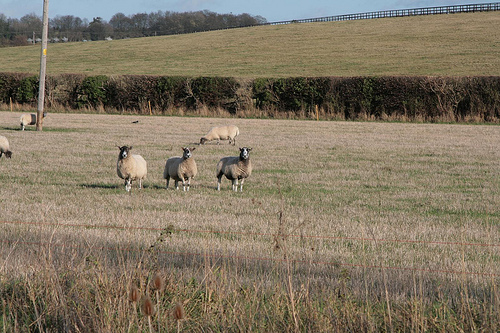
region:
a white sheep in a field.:
[110, 136, 150, 198]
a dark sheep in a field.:
[162, 138, 211, 200]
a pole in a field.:
[32, 0, 52, 136]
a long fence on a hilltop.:
[245, 0, 496, 28]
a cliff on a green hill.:
[0, 67, 494, 124]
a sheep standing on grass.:
[196, 140, 259, 201]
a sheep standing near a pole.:
[15, 101, 55, 136]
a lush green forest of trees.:
[0, 0, 265, 44]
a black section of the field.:
[132, 115, 157, 128]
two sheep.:
[0, 97, 61, 172]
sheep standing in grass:
[102, 138, 142, 203]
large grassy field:
[153, 34, 438, 71]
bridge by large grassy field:
[307, 2, 467, 21]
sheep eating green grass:
[197, 119, 244, 148]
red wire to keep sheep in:
[118, 216, 436, 300]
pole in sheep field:
[35, 12, 51, 134]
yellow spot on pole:
[41, 45, 49, 55]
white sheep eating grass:
[200, 112, 245, 144]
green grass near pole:
[45, 124, 90, 137]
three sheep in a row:
[110, 139, 261, 196]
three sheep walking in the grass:
[107, 141, 260, 193]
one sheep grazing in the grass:
[188, 120, 246, 147]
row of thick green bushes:
[0, 71, 497, 123]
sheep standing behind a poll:
[15, 105, 53, 128]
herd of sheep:
[0, 102, 279, 212]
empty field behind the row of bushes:
[8, 12, 497, 83]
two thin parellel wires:
[406, 233, 499, 284]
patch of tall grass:
[2, 238, 499, 332]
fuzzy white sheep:
[106, 139, 148, 188]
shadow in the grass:
[75, 171, 111, 190]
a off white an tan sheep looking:
[115, 141, 150, 189]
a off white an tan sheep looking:
[160, 147, 199, 187]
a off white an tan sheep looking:
[215, 146, 256, 188]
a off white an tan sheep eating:
[197, 123, 237, 143]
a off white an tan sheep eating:
[1, 136, 13, 161]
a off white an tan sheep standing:
[17, 109, 47, 126]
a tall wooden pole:
[38, 1, 51, 128]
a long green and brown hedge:
[2, 72, 498, 129]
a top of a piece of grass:
[151, 268, 168, 330]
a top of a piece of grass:
[129, 281, 144, 331]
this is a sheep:
[218, 142, 272, 201]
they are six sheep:
[1, 107, 244, 185]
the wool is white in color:
[130, 160, 141, 178]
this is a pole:
[38, 9, 47, 122]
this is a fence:
[266, 76, 401, 103]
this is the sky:
[266, 0, 324, 17]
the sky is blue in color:
[273, 3, 290, 10]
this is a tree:
[111, 9, 133, 36]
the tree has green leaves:
[95, 20, 105, 28]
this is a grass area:
[285, 180, 407, 247]